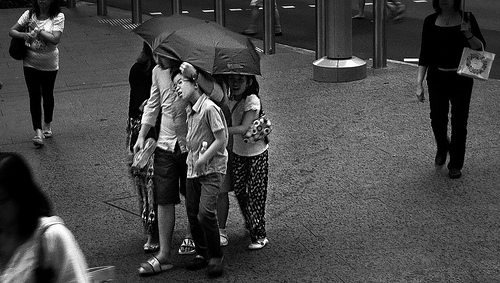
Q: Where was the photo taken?
A: It was taken at the sidewalk.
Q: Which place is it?
A: It is a sidewalk.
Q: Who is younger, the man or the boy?
A: The boy is younger than the man.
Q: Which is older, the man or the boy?
A: The man is older than the boy.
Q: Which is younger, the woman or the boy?
A: The boy is younger than the woman.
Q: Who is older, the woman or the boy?
A: The woman is older than the boy.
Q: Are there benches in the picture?
A: No, there are no benches.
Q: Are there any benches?
A: No, there are no benches.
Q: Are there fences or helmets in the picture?
A: No, there are no fences or helmets.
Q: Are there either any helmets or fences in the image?
A: No, there are no fences or helmets.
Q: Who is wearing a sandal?
A: The man is wearing a sandal.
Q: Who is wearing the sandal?
A: The man is wearing a sandal.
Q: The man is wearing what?
A: The man is wearing a sandal.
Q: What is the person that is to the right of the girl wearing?
A: The man is wearing a sandal.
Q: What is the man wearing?
A: The man is wearing a sandal.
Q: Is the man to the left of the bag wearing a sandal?
A: Yes, the man is wearing a sandal.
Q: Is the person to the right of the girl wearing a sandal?
A: Yes, the man is wearing a sandal.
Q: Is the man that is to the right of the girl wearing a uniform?
A: No, the man is wearing a sandal.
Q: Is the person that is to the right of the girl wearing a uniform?
A: No, the man is wearing a sandal.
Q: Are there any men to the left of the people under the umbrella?
A: Yes, there is a man to the left of the people.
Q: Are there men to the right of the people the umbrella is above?
A: No, the man is to the left of the people.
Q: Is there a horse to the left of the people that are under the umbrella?
A: No, there is a man to the left of the people.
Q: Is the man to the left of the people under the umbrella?
A: Yes, the man is to the left of the people.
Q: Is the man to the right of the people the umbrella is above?
A: No, the man is to the left of the people.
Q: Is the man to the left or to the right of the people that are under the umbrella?
A: The man is to the left of the people.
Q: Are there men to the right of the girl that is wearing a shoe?
A: Yes, there is a man to the right of the girl.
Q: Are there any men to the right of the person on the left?
A: Yes, there is a man to the right of the girl.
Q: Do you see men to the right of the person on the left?
A: Yes, there is a man to the right of the girl.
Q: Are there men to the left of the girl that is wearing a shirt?
A: No, the man is to the right of the girl.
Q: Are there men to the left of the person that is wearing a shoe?
A: No, the man is to the right of the girl.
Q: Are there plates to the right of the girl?
A: No, there is a man to the right of the girl.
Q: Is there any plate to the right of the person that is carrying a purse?
A: No, there is a man to the right of the girl.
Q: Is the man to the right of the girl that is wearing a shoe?
A: Yes, the man is to the right of the girl.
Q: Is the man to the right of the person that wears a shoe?
A: Yes, the man is to the right of the girl.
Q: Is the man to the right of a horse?
A: No, the man is to the right of the girl.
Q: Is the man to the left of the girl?
A: No, the man is to the right of the girl.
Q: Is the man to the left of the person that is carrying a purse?
A: No, the man is to the right of the girl.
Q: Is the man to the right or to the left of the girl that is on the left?
A: The man is to the right of the girl.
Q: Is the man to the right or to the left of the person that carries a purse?
A: The man is to the right of the girl.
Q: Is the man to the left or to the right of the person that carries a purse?
A: The man is to the right of the girl.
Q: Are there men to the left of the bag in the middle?
A: Yes, there is a man to the left of the bag.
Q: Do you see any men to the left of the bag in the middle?
A: Yes, there is a man to the left of the bag.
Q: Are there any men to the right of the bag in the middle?
A: No, the man is to the left of the bag.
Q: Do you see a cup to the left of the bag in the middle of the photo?
A: No, there is a man to the left of the bag.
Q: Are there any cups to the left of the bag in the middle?
A: No, there is a man to the left of the bag.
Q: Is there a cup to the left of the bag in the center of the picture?
A: No, there is a man to the left of the bag.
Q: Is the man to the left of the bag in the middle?
A: Yes, the man is to the left of the bag.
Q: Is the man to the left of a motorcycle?
A: No, the man is to the left of the bag.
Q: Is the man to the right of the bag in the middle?
A: No, the man is to the left of the bag.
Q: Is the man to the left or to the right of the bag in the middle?
A: The man is to the left of the bag.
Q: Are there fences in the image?
A: No, there are no fences.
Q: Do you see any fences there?
A: No, there are no fences.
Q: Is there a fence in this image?
A: No, there are no fences.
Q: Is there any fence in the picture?
A: No, there are no fences.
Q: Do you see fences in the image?
A: No, there are no fences.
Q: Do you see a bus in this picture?
A: No, there are no buses.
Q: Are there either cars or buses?
A: No, there are no buses or cars.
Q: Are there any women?
A: Yes, there is a woman.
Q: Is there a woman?
A: Yes, there is a woman.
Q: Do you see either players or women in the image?
A: Yes, there is a woman.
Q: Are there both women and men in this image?
A: Yes, there are both a woman and a man.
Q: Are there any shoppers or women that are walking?
A: Yes, the woman is walking.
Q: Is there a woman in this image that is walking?
A: Yes, there is a woman that is walking.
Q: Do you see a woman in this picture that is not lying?
A: Yes, there is a woman that is walking .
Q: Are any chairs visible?
A: No, there are no chairs.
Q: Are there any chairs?
A: No, there are no chairs.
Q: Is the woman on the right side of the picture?
A: Yes, the woman is on the right of the image.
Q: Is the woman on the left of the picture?
A: No, the woman is on the right of the image.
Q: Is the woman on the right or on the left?
A: The woman is on the right of the image.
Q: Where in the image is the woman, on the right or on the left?
A: The woman is on the right of the image.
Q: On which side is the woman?
A: The woman is on the right of the image.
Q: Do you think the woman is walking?
A: Yes, the woman is walking.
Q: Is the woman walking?
A: Yes, the woman is walking.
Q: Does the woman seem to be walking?
A: Yes, the woman is walking.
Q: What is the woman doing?
A: The woman is walking.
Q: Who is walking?
A: The woman is walking.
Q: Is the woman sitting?
A: No, the woman is walking.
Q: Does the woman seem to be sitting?
A: No, the woman is walking.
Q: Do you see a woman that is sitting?
A: No, there is a woman but she is walking.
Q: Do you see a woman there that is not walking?
A: No, there is a woman but she is walking.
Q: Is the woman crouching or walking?
A: The woman is walking.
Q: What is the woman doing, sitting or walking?
A: The woman is walking.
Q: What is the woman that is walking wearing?
A: The woman is wearing a shirt.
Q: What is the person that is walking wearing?
A: The woman is wearing a shirt.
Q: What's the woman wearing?
A: The woman is wearing a shirt.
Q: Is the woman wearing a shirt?
A: Yes, the woman is wearing a shirt.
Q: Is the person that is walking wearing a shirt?
A: Yes, the woman is wearing a shirt.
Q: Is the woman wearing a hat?
A: No, the woman is wearing a shirt.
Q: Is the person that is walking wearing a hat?
A: No, the woman is wearing a shirt.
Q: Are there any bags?
A: Yes, there is a bag.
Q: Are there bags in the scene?
A: Yes, there is a bag.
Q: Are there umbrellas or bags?
A: Yes, there is a bag.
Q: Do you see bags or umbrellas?
A: Yes, there is a bag.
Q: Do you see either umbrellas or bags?
A: Yes, there is a bag.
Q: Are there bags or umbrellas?
A: Yes, there is a bag.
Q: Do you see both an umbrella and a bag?
A: Yes, there are both a bag and an umbrella.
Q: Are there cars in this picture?
A: No, there are no cars.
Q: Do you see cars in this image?
A: No, there are no cars.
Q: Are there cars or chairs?
A: No, there are no cars or chairs.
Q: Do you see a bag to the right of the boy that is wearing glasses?
A: Yes, there is a bag to the right of the boy.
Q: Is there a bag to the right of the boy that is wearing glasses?
A: Yes, there is a bag to the right of the boy.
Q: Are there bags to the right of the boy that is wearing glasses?
A: Yes, there is a bag to the right of the boy.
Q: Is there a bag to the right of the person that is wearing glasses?
A: Yes, there is a bag to the right of the boy.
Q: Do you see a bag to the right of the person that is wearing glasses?
A: Yes, there is a bag to the right of the boy.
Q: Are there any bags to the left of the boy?
A: No, the bag is to the right of the boy.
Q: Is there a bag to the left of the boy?
A: No, the bag is to the right of the boy.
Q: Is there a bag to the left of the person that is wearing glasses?
A: No, the bag is to the right of the boy.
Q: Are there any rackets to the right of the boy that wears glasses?
A: No, there is a bag to the right of the boy.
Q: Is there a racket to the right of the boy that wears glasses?
A: No, there is a bag to the right of the boy.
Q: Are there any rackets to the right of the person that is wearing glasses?
A: No, there is a bag to the right of the boy.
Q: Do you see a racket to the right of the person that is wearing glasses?
A: No, there is a bag to the right of the boy.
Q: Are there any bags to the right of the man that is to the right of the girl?
A: Yes, there is a bag to the right of the man.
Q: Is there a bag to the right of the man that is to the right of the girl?
A: Yes, there is a bag to the right of the man.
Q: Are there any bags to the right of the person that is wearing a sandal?
A: Yes, there is a bag to the right of the man.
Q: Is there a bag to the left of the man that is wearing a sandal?
A: No, the bag is to the right of the man.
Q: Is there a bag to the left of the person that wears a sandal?
A: No, the bag is to the right of the man.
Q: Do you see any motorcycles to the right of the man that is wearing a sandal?
A: No, there is a bag to the right of the man.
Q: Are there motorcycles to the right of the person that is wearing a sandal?
A: No, there is a bag to the right of the man.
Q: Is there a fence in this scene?
A: No, there are no fences.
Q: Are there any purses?
A: Yes, there is a purse.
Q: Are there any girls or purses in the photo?
A: Yes, there is a purse.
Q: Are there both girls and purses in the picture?
A: Yes, there are both a purse and a girl.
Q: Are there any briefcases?
A: No, there are no briefcases.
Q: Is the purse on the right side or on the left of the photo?
A: The purse is on the left of the image.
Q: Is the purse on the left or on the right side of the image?
A: The purse is on the left of the image.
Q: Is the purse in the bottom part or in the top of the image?
A: The purse is in the top of the image.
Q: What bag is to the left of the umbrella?
A: The bag is a purse.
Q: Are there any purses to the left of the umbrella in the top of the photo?
A: Yes, there is a purse to the left of the umbrella.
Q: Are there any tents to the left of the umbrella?
A: No, there is a purse to the left of the umbrella.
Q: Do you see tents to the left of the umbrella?
A: No, there is a purse to the left of the umbrella.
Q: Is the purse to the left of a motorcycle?
A: No, the purse is to the left of an umbrella.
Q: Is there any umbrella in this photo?
A: Yes, there is an umbrella.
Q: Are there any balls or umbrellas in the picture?
A: Yes, there is an umbrella.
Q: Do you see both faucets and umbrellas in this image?
A: No, there is an umbrella but no faucets.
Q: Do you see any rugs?
A: No, there are no rugs.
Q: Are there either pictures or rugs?
A: No, there are no rugs or pictures.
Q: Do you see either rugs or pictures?
A: No, there are no rugs or pictures.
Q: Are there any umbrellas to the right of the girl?
A: Yes, there is an umbrella to the right of the girl.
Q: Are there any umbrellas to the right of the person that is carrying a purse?
A: Yes, there is an umbrella to the right of the girl.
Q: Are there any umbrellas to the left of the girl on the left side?
A: No, the umbrella is to the right of the girl.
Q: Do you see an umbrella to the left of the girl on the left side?
A: No, the umbrella is to the right of the girl.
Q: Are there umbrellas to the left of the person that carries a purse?
A: No, the umbrella is to the right of the girl.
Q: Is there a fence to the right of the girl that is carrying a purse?
A: No, there is an umbrella to the right of the girl.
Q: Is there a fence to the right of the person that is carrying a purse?
A: No, there is an umbrella to the right of the girl.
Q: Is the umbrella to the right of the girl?
A: Yes, the umbrella is to the right of the girl.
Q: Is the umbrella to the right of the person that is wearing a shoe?
A: Yes, the umbrella is to the right of the girl.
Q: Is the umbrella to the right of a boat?
A: No, the umbrella is to the right of the girl.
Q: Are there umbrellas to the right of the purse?
A: Yes, there is an umbrella to the right of the purse.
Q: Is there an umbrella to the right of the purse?
A: Yes, there is an umbrella to the right of the purse.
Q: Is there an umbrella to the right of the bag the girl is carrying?
A: Yes, there is an umbrella to the right of the purse.